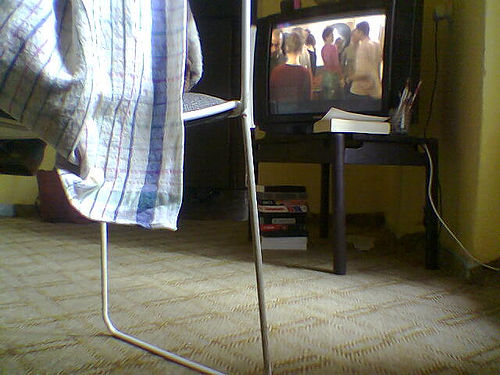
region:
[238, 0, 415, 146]
black frame on television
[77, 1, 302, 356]
white frame on chair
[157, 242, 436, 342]
brown and tan floor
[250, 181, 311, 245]
videocassettes piled on floor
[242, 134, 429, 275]
television on black table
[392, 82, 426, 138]
white pens in cup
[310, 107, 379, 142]
book sitting on table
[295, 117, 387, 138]
book in front of tv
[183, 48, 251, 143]
grey seat on chair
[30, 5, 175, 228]
blue and white shirt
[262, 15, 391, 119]
tv screen with people on it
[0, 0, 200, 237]
blue and white towel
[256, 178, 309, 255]
vhs movies under stand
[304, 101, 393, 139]
book on the stand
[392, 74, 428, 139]
pencils in a cup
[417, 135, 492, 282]
white wire for the tv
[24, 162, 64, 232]
red pillow on the floor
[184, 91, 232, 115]
cushion of the chair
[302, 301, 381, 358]
tan rug with yellow lines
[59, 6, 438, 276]
a television on a stand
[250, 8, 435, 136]
the TV set is small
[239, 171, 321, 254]
books on the floor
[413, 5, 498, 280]
a wire in the wall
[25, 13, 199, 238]
a blue and white towel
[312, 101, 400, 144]
a book on a chair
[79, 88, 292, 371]
the legs of a chair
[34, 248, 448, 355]
tan carpeting on the floor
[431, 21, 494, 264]
a yellow wall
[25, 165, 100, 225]
a pink purse in the background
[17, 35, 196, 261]
blue and white plaid cloth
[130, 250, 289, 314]
silver bottom of chair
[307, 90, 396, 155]
book on corner on table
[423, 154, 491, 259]
white cord on table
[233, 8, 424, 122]
black table on table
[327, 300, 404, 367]
gran and brown square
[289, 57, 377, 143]
people showing on the TV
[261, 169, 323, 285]
a small stack of books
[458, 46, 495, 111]
yellow painted living room wall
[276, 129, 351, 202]
black plastic TV table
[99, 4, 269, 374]
Thin chair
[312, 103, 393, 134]
Small book on top of the stand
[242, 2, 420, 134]
Television screen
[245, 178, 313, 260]
Group of books on the ground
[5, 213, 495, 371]
Ground with carpet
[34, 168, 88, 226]
Small red laptop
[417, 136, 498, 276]
White wire connected from the television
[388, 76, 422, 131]
Cup of writing utensils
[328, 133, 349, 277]
Wooden pole of the stand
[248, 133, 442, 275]
Television stand